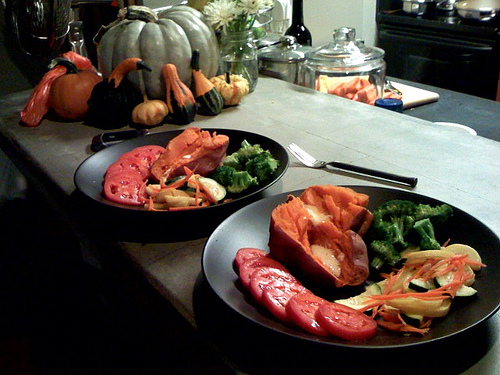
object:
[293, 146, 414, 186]
fork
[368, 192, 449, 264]
broccoli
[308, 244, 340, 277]
butter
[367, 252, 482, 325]
carrot slices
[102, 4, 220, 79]
pumpkin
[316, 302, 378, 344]
slice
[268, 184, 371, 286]
sweet potato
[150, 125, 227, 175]
sweet potato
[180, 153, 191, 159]
butter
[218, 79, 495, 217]
table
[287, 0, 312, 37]
bottle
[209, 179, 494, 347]
plate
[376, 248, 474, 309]
vegetables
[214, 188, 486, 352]
bowl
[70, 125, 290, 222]
plate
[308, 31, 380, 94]
glass jar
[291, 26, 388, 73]
lid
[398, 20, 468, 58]
pull handle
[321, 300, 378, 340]
tomatoes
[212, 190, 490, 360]
dish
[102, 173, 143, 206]
tomatoes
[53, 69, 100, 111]
pumpkin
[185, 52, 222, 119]
gourd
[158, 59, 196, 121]
gourd